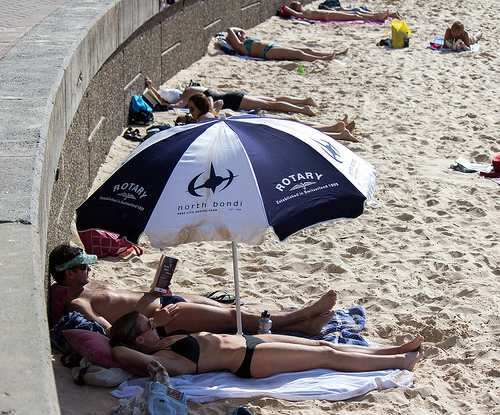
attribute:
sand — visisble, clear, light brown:
[67, 1, 499, 414]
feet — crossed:
[297, 290, 338, 340]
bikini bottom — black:
[235, 330, 258, 379]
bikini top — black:
[170, 330, 199, 364]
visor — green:
[58, 252, 99, 270]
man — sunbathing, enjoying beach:
[50, 246, 335, 337]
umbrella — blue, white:
[77, 116, 371, 245]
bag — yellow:
[388, 17, 407, 49]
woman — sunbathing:
[107, 310, 424, 376]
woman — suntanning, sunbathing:
[220, 25, 339, 64]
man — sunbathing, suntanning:
[444, 20, 477, 49]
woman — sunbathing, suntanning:
[177, 81, 318, 115]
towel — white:
[134, 353, 410, 402]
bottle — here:
[259, 310, 272, 334]